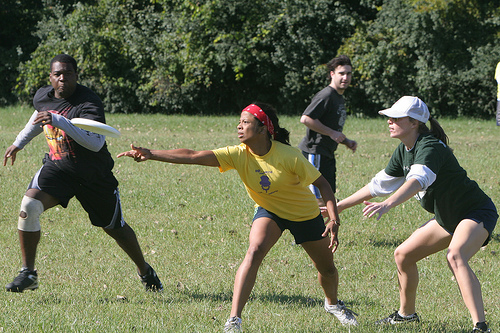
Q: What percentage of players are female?
A: 50.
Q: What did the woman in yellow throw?
A: Frisbee.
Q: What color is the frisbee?
A: White.